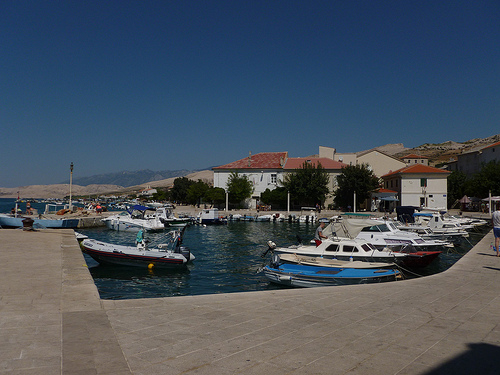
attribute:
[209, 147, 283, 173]
roof — red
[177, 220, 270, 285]
water — deep blue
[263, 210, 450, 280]
boats — parked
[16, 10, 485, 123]
sky — blue, clear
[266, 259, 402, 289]
boats — docked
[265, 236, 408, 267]
boats — docked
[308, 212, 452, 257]
boats — docked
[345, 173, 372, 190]
leaves — green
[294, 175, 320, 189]
leaves — green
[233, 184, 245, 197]
leaves — green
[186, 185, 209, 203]
leaves — green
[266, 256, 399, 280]
top — blue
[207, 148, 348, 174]
roof — red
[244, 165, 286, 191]
wall — white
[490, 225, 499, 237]
shorts — blue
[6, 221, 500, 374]
tile deck — tiled